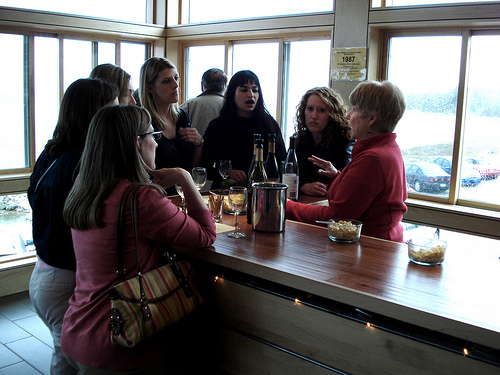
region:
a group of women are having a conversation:
[8, 44, 413, 269]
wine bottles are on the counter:
[246, 125, 299, 202]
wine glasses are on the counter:
[170, 158, 253, 243]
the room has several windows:
[1, 29, 499, 207]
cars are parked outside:
[403, 143, 494, 195]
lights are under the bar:
[207, 263, 483, 365]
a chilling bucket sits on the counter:
[251, 178, 286, 238]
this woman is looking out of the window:
[188, 65, 230, 119]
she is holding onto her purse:
[100, 185, 194, 344]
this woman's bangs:
[220, 70, 282, 89]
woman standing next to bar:
[59, 104, 214, 374]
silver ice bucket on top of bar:
[251, 183, 287, 234]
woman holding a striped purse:
[108, 182, 210, 349]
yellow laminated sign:
[329, 43, 367, 82]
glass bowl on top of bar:
[407, 237, 447, 260]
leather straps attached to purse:
[113, 182, 189, 320]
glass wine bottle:
[281, 135, 299, 200]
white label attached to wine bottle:
[282, 173, 300, 200]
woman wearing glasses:
[66, 105, 217, 374]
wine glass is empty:
[228, 183, 248, 238]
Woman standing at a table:
[339, 63, 421, 271]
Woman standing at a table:
[274, 63, 337, 200]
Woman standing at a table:
[220, 60, 294, 234]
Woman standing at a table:
[142, 57, 224, 208]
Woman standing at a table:
[83, 55, 144, 107]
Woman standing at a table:
[20, 64, 98, 359]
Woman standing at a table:
[63, 99, 255, 371]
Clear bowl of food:
[399, 223, 464, 283]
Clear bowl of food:
[316, 215, 371, 244]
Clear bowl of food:
[218, 181, 253, 221]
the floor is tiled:
[5, 313, 40, 363]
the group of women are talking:
[75, 65, 382, 185]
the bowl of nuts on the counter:
[387, 227, 455, 269]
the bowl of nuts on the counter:
[315, 211, 372, 242]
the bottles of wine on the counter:
[240, 131, 302, 178]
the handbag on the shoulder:
[106, 185, 226, 350]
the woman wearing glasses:
[101, 101, 161, 146]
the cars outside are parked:
[410, 151, 495, 186]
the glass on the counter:
[210, 180, 245, 250]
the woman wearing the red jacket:
[322, 136, 425, 239]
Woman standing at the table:
[336, 68, 413, 237]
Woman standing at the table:
[280, 74, 344, 231]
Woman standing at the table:
[220, 64, 295, 203]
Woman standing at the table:
[184, 60, 233, 160]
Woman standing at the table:
[140, 44, 209, 171]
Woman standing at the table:
[67, 107, 199, 346]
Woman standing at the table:
[25, 70, 128, 365]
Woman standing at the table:
[92, 51, 162, 130]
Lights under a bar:
[206, 266, 461, 373]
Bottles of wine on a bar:
[242, 125, 321, 265]